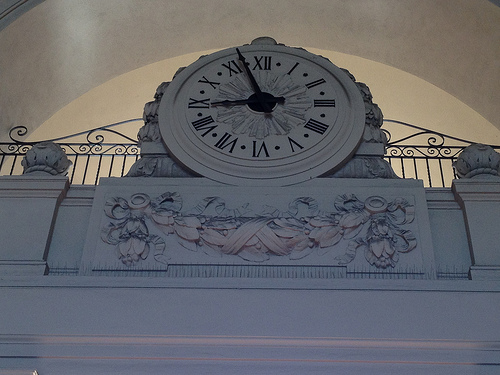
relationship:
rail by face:
[364, 126, 459, 183] [183, 50, 338, 162]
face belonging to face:
[183, 50, 338, 162] [183, 50, 338, 162]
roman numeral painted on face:
[250, 54, 271, 69] [183, 50, 338, 162]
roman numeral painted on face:
[302, 77, 327, 90] [183, 50, 338, 162]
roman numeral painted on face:
[302, 116, 328, 136] [183, 50, 338, 162]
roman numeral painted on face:
[213, 130, 238, 154] [183, 50, 338, 162]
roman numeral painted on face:
[285, 135, 305, 154] [183, 50, 338, 162]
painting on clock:
[101, 163, 444, 285] [88, 168, 428, 290]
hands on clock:
[231, 55, 278, 136] [170, 41, 342, 181]